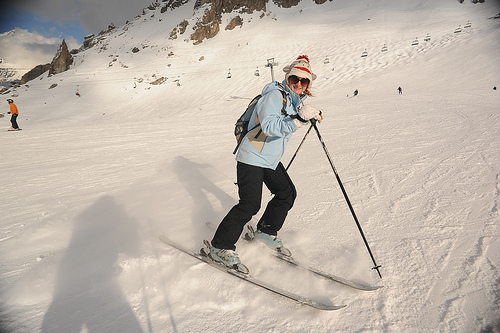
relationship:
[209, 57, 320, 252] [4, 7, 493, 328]
man on mountain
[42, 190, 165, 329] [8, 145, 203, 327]
shadows on snow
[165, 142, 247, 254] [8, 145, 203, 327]
shadows on snow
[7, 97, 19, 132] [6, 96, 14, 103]
man wearing cap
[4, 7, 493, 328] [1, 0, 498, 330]
mountain covered in snow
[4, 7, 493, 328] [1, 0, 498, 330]
mountain covered with snow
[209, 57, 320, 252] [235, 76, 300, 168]
man wearing jacket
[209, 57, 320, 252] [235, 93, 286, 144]
man carrying pack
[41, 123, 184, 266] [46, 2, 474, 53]
snow on mountain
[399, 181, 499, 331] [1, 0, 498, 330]
tracks in snow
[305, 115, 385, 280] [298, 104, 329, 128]
ski pole in hand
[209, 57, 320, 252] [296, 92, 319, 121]
man wearing gloves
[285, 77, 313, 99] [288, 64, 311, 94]
glasses on woman's face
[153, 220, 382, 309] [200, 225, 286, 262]
skis on feet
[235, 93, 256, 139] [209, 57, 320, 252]
pack on man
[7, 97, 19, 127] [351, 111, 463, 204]
man skiing on snow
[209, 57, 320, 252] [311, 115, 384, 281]
man holding ski pole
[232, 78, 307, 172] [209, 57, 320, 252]
jacket on man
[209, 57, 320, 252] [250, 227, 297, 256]
man has foot